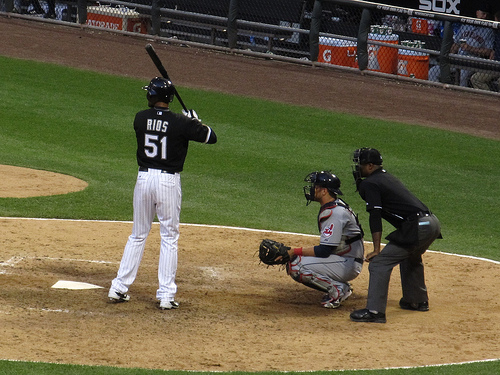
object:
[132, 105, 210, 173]
jersey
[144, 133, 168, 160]
number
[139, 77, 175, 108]
helmet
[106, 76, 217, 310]
batter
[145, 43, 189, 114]
bat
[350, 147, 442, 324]
umpire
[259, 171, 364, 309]
catcher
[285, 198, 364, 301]
uniform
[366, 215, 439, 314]
slacks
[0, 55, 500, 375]
field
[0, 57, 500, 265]
grass